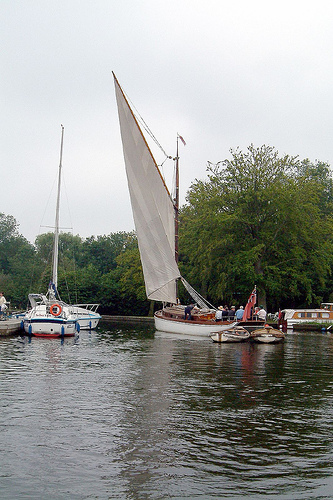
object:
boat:
[250, 325, 285, 343]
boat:
[209, 326, 250, 343]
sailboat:
[110, 70, 238, 336]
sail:
[106, 70, 181, 308]